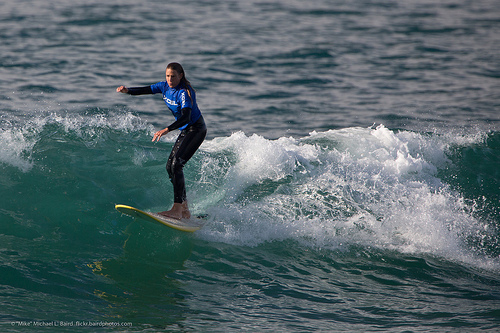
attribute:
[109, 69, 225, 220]
woman — standing, surfing, wet, balancing, barefoot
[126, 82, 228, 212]
wetsuit — black, blue, white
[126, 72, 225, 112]
hair — long, wet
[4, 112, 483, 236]
wave — splashing, big, crashing, white, cresting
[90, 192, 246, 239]
surfboard — yellow, white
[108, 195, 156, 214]
nose — yellow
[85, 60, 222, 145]
arms — extended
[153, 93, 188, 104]
letters — white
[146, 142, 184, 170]
knees — bent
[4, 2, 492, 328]
water — blue, green